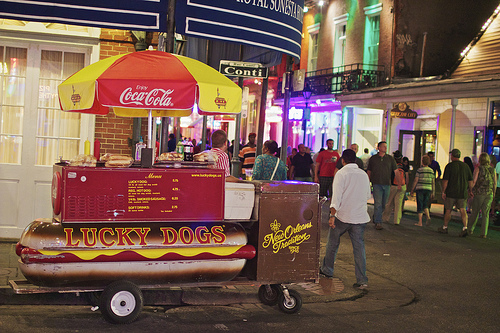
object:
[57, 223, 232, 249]
writing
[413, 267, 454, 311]
road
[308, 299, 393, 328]
road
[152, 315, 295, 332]
road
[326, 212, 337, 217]
watch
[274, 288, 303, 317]
wheel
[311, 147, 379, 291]
man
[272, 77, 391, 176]
light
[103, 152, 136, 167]
buns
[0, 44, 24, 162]
window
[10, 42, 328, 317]
cart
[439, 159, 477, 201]
shirt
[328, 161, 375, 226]
shirt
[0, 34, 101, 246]
door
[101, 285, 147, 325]
wheel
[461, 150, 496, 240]
people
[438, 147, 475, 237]
people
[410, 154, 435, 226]
people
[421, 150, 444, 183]
people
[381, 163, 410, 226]
people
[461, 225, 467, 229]
sock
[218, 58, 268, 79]
sign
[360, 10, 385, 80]
window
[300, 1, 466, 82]
building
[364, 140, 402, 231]
man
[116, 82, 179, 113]
logo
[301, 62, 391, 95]
black balcony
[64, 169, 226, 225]
menu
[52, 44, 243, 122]
umbrella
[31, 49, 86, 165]
window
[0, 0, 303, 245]
building